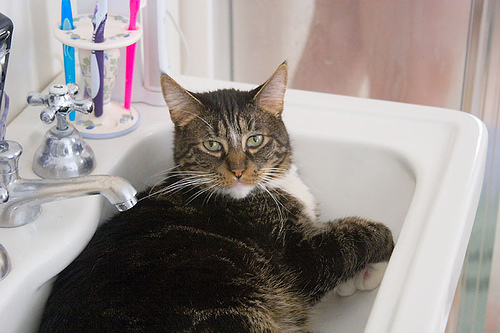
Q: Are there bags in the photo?
A: No, there are no bags.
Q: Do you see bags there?
A: No, there are no bags.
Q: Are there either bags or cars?
A: No, there are no bags or cars.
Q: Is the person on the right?
A: Yes, the person is on the right of the image.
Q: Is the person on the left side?
A: No, the person is on the right of the image.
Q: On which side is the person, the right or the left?
A: The person is on the right of the image.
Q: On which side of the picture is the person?
A: The person is on the right of the image.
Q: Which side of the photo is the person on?
A: The person is on the right of the image.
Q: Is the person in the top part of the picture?
A: Yes, the person is in the top of the image.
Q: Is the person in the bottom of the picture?
A: No, the person is in the top of the image.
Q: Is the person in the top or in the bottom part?
A: The person is in the top of the image.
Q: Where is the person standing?
A: The person is standing in the shower.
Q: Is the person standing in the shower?
A: Yes, the person is standing in the shower.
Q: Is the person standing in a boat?
A: No, the person is standing in the shower.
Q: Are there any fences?
A: No, there are no fences.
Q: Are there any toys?
A: No, there are no toys.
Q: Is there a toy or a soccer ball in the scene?
A: No, there are no toys or soccer balls.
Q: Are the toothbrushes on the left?
A: Yes, the toothbrushes are on the left of the image.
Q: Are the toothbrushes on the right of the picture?
A: No, the toothbrushes are on the left of the image.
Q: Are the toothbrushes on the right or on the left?
A: The toothbrushes are on the left of the image.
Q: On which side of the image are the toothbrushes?
A: The toothbrushes are on the left of the image.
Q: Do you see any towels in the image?
A: No, there are no towels.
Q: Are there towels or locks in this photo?
A: No, there are no towels or locks.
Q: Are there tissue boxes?
A: No, there are no tissue boxes.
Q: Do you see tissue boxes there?
A: No, there are no tissue boxes.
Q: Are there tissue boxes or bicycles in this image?
A: No, there are no tissue boxes or bicycles.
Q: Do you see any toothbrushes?
A: Yes, there is a toothbrush.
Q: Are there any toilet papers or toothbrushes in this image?
A: Yes, there is a toothbrush.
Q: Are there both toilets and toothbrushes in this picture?
A: No, there is a toothbrush but no toilets.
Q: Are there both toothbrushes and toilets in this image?
A: No, there is a toothbrush but no toilets.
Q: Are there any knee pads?
A: No, there are no knee pads.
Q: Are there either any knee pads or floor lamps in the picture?
A: No, there are no knee pads or floor lamps.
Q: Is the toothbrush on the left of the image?
A: Yes, the toothbrush is on the left of the image.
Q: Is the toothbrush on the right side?
A: No, the toothbrush is on the left of the image.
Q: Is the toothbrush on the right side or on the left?
A: The toothbrush is on the left of the image.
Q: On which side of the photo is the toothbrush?
A: The toothbrush is on the left of the image.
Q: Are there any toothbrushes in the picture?
A: Yes, there is a toothbrush.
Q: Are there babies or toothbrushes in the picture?
A: Yes, there is a toothbrush.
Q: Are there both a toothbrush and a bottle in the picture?
A: No, there is a toothbrush but no bottles.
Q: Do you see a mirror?
A: No, there are no mirrors.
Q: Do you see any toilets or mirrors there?
A: No, there are no mirrors or toilets.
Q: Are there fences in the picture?
A: No, there are no fences.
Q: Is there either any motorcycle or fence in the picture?
A: No, there are no fences or motorcycles.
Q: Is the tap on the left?
A: Yes, the tap is on the left of the image.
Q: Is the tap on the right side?
A: No, the tap is on the left of the image.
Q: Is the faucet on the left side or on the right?
A: The faucet is on the left of the image.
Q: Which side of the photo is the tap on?
A: The tap is on the left of the image.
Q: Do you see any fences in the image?
A: No, there are no fences.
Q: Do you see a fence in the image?
A: No, there are no fences.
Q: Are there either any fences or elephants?
A: No, there are no fences or elephants.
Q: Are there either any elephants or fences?
A: No, there are no fences or elephants.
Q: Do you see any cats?
A: Yes, there is a cat.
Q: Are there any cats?
A: Yes, there is a cat.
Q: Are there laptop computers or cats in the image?
A: Yes, there is a cat.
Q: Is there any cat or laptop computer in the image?
A: Yes, there is a cat.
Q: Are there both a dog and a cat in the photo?
A: No, there is a cat but no dogs.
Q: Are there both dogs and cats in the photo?
A: No, there is a cat but no dogs.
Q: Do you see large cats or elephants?
A: Yes, there is a large cat.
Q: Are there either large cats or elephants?
A: Yes, there is a large cat.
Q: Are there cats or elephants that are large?
A: Yes, the cat is large.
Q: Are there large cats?
A: Yes, there is a large cat.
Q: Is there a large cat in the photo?
A: Yes, there is a large cat.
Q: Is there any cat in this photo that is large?
A: Yes, there is a cat that is large.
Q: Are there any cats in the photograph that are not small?
A: Yes, there is a large cat.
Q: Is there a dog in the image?
A: No, there are no dogs.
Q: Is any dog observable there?
A: No, there are no dogs.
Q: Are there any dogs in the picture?
A: No, there are no dogs.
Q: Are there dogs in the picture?
A: No, there are no dogs.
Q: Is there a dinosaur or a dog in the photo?
A: No, there are no dogs or dinosaurs.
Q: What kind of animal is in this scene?
A: The animal is a cat.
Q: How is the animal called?
A: The animal is a cat.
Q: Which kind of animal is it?
A: The animal is a cat.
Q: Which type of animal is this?
A: This is a cat.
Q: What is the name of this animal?
A: This is a cat.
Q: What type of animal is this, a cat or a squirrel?
A: This is a cat.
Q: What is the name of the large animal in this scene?
A: The animal is a cat.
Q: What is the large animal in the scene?
A: The animal is a cat.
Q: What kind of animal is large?
A: The animal is a cat.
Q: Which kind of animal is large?
A: The animal is a cat.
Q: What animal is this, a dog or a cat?
A: This is a cat.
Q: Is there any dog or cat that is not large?
A: No, there is a cat but it is large.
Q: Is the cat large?
A: Yes, the cat is large.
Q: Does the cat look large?
A: Yes, the cat is large.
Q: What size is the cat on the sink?
A: The cat is large.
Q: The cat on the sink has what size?
A: The cat is large.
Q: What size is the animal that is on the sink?
A: The cat is large.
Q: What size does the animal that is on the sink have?
A: The cat has large size.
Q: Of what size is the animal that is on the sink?
A: The cat is large.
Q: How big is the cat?
A: The cat is large.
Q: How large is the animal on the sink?
A: The cat is large.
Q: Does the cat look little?
A: No, the cat is large.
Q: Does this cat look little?
A: No, the cat is large.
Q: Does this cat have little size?
A: No, the cat is large.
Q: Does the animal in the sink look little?
A: No, the cat is large.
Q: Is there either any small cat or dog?
A: No, there is a cat but it is large.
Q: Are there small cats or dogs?
A: No, there is a cat but it is large.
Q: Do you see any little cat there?
A: No, there is a cat but it is large.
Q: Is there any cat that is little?
A: No, there is a cat but it is large.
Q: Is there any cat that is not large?
A: No, there is a cat but it is large.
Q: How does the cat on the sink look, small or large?
A: The cat is large.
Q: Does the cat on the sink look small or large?
A: The cat is large.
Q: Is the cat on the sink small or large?
A: The cat is large.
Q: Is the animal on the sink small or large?
A: The cat is large.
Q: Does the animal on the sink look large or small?
A: The cat is large.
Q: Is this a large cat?
A: Yes, this is a large cat.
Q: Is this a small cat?
A: No, this is a large cat.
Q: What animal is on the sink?
A: The cat is on the sink.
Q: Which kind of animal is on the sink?
A: The animal is a cat.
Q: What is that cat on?
A: The cat is on the sink.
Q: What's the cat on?
A: The cat is on the sink.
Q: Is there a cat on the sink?
A: Yes, there is a cat on the sink.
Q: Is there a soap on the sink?
A: No, there is a cat on the sink.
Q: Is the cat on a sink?
A: Yes, the cat is on a sink.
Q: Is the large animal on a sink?
A: Yes, the cat is on a sink.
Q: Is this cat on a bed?
A: No, the cat is on a sink.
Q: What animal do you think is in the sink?
A: The cat is in the sink.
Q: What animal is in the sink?
A: The animal is a cat.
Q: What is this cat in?
A: The cat is in the sink.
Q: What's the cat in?
A: The cat is in the sink.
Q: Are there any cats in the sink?
A: Yes, there is a cat in the sink.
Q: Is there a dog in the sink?
A: No, there is a cat in the sink.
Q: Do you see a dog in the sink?
A: No, there is a cat in the sink.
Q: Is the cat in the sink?
A: Yes, the cat is in the sink.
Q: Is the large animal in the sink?
A: Yes, the cat is in the sink.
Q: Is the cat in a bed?
A: No, the cat is in the sink.